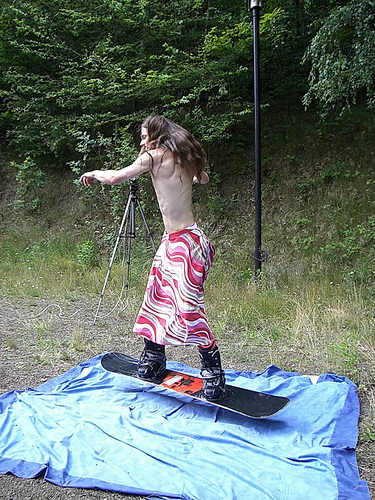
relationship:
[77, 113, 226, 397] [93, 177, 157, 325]
person in front of camera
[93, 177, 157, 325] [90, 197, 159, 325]
camera on tripod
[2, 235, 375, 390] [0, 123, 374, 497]
grass on ground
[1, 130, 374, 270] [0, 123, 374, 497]
plants on ground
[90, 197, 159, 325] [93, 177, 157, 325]
tripod has camera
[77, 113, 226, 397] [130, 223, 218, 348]
person has skirt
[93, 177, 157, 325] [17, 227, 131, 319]
camera has cable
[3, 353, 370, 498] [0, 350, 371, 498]
blanket has wrinkles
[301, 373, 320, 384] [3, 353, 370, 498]
pad under blanket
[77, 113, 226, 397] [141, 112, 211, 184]
person has hair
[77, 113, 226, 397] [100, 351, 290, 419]
person standing on snowboard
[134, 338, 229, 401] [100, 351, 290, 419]
boots are on snowboard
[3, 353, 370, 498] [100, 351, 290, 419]
blanket under snowboard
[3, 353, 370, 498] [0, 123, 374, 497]
blanket laying on ground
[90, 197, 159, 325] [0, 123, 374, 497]
tripod standing on ground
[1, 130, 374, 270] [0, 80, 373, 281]
plants are on a hill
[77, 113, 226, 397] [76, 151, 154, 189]
person has left arm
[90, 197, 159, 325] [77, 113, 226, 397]
tripod behind person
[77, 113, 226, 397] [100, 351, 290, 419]
person riding snowboard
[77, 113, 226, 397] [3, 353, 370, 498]
person on blanket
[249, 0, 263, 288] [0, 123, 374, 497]
pole in ground